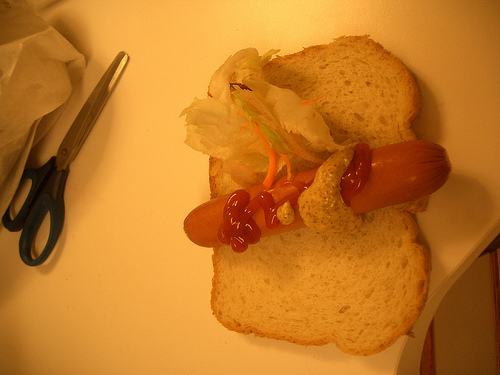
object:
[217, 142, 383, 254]
condiments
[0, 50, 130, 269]
scissors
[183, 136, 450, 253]
hot dog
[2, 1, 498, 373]
white table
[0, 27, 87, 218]
napkin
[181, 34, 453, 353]
sandwich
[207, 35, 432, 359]
bread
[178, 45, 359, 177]
lettuce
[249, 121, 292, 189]
carrot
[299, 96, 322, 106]
carrot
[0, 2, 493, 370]
counter